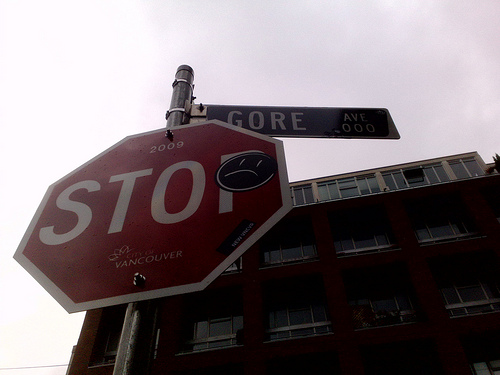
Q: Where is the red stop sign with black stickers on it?
A: On the pole.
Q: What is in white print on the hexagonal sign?
A: The word stop.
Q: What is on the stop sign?
A: Stickers.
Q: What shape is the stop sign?
A: An octagon.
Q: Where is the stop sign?
A: Vancouver.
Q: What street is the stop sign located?
A: Gore Ave.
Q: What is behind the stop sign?
A: A multi-story building.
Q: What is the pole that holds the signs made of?
A: Metal.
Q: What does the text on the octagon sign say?
A: Stop.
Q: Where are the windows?
A: On the building behind the stop sign.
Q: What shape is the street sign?
A: Rectangular with rounded corners.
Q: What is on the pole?
A: Signs.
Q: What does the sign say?
A: Stop.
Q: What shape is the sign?
A: Octagon.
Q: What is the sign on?
A: A pole.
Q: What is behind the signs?
A: A building.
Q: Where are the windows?
A: On the building.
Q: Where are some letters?
A: On the signs.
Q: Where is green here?
A: On the top sign.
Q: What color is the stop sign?
A: Red.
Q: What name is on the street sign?
A: Gore.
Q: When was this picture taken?
A: During the day.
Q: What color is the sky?
A: Blue.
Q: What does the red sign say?
A: Stop.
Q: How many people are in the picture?
A: Zero.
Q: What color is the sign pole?
A: Silver.